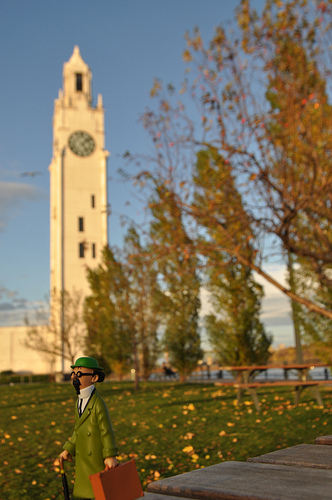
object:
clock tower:
[47, 45, 111, 373]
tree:
[81, 243, 135, 382]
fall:
[0, 0, 332, 500]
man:
[58, 356, 119, 500]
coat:
[62, 388, 117, 500]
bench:
[215, 360, 332, 412]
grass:
[0, 380, 332, 500]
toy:
[58, 356, 119, 499]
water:
[268, 369, 281, 377]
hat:
[69, 355, 107, 371]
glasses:
[70, 370, 96, 378]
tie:
[79, 398, 84, 418]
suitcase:
[89, 456, 145, 500]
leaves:
[219, 430, 226, 438]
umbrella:
[57, 456, 74, 500]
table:
[215, 361, 332, 413]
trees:
[183, 141, 275, 385]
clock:
[67, 129, 97, 159]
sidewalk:
[140, 435, 332, 500]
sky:
[0, 0, 332, 349]